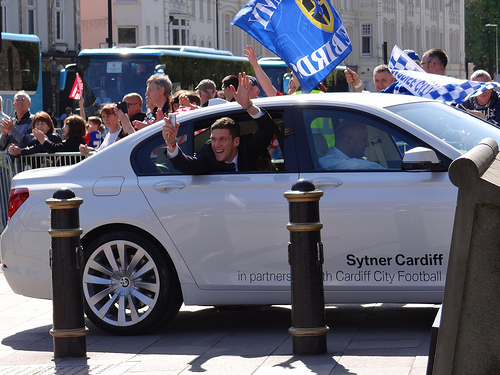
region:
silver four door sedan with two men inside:
[2, 78, 494, 326]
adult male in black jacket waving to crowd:
[152, 77, 284, 175]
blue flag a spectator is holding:
[224, 0, 363, 88]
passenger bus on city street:
[72, 44, 257, 130]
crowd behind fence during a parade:
[2, 88, 192, 155]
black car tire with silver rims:
[72, 211, 187, 337]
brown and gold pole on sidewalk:
[275, 178, 338, 368]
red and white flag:
[63, 70, 89, 102]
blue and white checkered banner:
[384, 39, 492, 116]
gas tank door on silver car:
[82, 167, 134, 202]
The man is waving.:
[142, 63, 292, 193]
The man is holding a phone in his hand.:
[150, 100, 192, 172]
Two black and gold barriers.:
[32, 170, 352, 372]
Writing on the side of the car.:
[231, 235, 456, 300]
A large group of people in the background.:
[0, 35, 497, 175]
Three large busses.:
[0, 25, 345, 105]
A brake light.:
[2, 165, 32, 225]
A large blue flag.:
[230, 0, 361, 90]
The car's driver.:
[310, 110, 385, 171]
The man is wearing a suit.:
[147, 81, 277, 191]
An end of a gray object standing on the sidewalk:
[428, 133, 498, 373]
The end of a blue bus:
[1, 26, 51, 114]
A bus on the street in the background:
[78, 43, 258, 105]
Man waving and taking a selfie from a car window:
[153, 70, 275, 178]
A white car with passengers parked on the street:
[0, 90, 499, 333]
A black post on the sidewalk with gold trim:
[37, 183, 94, 361]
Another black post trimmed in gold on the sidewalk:
[275, 181, 335, 356]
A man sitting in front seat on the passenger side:
[317, 109, 404, 184]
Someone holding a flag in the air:
[229, 0, 363, 91]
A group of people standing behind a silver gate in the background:
[1, 63, 141, 170]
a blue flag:
[228, 1, 373, 98]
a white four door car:
[6, 91, 491, 333]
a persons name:
[337, 242, 454, 272]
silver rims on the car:
[79, 237, 161, 328]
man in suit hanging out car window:
[149, 61, 291, 191]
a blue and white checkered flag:
[382, 42, 497, 109]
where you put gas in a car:
[81, 171, 131, 201]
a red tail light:
[3, 182, 43, 229]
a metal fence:
[2, 141, 97, 183]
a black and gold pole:
[283, 172, 340, 363]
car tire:
[75, 217, 181, 338]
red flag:
[57, 61, 102, 113]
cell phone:
[160, 107, 185, 132]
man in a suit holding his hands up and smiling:
[128, 69, 294, 181]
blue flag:
[223, 0, 368, 95]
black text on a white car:
[325, 241, 451, 284]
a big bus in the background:
[52, 40, 254, 116]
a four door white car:
[0, 82, 496, 292]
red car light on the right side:
[0, 181, 31, 232]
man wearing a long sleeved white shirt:
[305, 105, 392, 182]